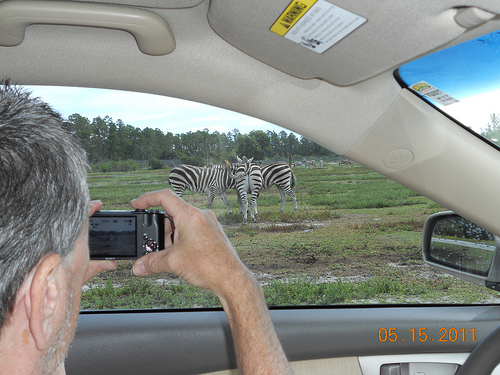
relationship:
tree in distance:
[151, 128, 191, 160] [100, 96, 349, 292]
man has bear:
[21, 79, 197, 371] [23, 275, 99, 368]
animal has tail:
[224, 155, 264, 226] [232, 162, 263, 194]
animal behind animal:
[231, 172, 269, 198] [224, 155, 264, 226]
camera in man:
[78, 191, 179, 267] [21, 79, 197, 371]